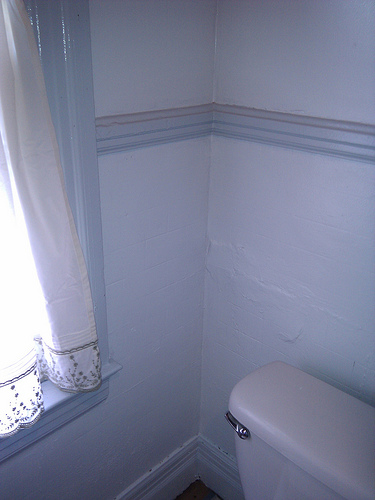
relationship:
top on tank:
[224, 352, 374, 497] [224, 363, 374, 499]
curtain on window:
[1, 0, 103, 437] [8, 16, 129, 459]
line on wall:
[216, 118, 370, 156] [91, 1, 372, 494]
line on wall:
[94, 120, 211, 143] [91, 1, 372, 494]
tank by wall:
[212, 335, 373, 491] [198, 4, 373, 495]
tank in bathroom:
[225, 360, 375, 499] [1, 0, 373, 498]